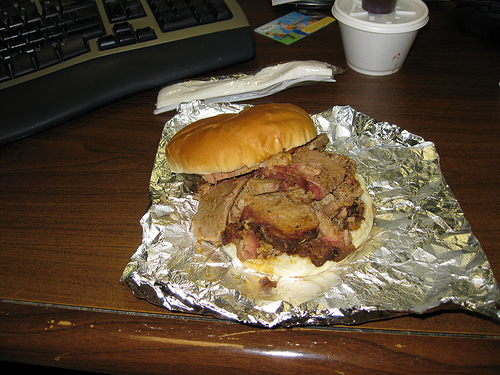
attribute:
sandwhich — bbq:
[173, 105, 375, 274]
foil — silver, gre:
[122, 96, 498, 324]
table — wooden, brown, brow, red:
[1, 40, 499, 370]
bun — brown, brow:
[161, 105, 336, 164]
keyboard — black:
[0, 0, 243, 142]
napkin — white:
[151, 72, 341, 97]